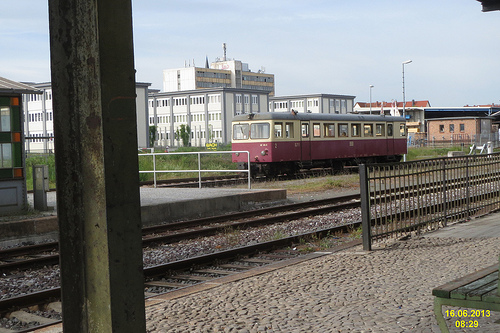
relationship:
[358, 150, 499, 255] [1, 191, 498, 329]
fence near track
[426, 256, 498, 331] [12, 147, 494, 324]
bench near track